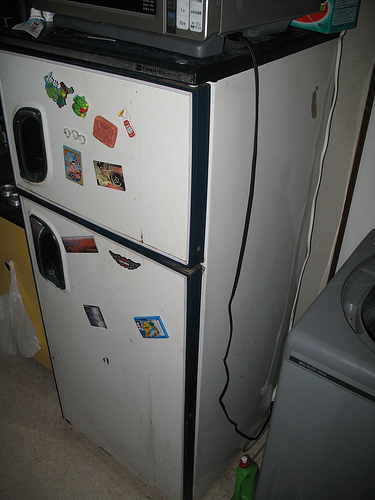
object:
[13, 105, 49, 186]
handle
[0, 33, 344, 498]
freezer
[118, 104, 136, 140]
magnet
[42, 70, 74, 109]
magnet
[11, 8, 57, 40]
toothpaste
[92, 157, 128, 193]
rectangular magnet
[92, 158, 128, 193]
colorful magnet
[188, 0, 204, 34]
button menu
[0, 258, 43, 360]
plastic bag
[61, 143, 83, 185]
magnet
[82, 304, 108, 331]
magnet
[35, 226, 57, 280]
door handle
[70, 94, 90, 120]
stickers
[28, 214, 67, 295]
door handle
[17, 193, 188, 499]
door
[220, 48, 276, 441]
cord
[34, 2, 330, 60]
microwave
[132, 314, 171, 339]
magnet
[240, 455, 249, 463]
cap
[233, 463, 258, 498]
green bottle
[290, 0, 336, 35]
soap box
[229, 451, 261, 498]
detergent bottle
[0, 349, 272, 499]
floor